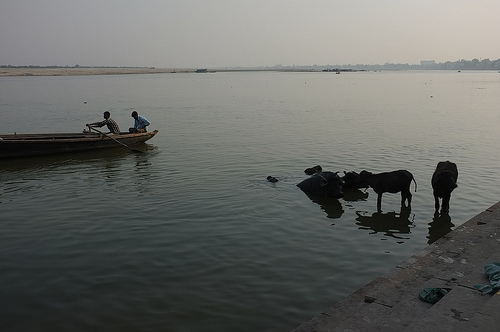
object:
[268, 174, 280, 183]
stone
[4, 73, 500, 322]
water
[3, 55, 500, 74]
line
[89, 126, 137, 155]
oar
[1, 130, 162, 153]
boat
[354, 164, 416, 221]
cow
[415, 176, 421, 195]
tail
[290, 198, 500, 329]
cluster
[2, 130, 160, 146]
edge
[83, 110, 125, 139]
man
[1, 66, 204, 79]
land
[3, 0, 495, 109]
distance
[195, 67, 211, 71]
house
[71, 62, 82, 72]
house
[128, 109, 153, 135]
man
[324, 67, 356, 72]
building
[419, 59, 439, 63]
building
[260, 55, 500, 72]
trees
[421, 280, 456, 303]
sandals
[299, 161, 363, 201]
trash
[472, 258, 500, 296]
clothes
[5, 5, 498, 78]
view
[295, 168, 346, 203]
cow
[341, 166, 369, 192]
cow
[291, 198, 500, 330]
wall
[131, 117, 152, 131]
shirt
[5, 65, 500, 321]
lake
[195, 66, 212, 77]
building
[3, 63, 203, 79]
shore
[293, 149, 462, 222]
group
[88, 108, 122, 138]
person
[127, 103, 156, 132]
person